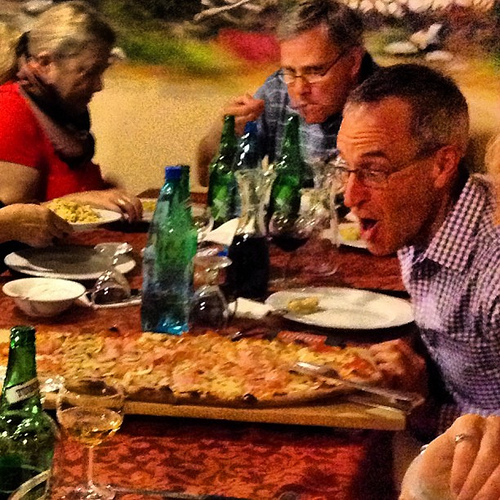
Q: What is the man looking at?
A: Pizza.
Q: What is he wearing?
A: Glasses.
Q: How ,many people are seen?
A: 3.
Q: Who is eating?
A: The man at the far end.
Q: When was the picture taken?
A: During the day.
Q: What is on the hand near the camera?
A: Ring.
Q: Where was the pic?
A: At a resturant.